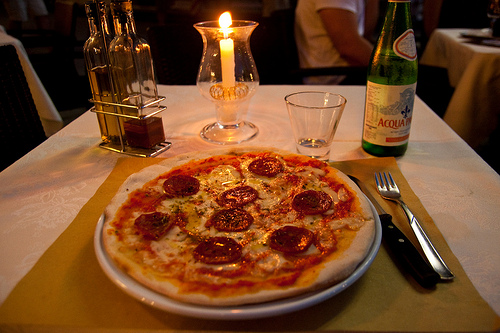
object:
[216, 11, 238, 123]
candle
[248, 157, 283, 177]
pepperoni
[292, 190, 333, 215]
pepperoni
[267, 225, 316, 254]
pepperoni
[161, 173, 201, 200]
pepperoni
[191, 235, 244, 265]
pepperoni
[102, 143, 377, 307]
pizza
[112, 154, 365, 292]
cheese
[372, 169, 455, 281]
fork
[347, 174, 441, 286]
knife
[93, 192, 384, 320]
plate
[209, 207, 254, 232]
pepperoni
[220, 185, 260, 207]
pepperoni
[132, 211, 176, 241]
pepperoni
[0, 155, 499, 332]
mat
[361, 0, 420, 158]
bottle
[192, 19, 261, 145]
container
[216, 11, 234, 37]
flame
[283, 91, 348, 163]
glass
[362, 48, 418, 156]
water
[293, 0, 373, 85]
person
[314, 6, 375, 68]
arm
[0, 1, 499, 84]
background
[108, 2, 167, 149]
container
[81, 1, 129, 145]
container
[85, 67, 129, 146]
oil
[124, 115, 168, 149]
vinegar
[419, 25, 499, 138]
table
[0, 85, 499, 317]
tablecloth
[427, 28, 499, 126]
tablecloth